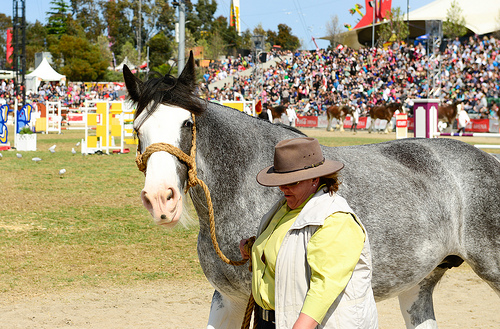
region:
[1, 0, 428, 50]
blue of daytime sky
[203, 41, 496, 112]
crowd sitting in stands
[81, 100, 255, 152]
white poles on yellow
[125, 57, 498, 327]
side of walking horse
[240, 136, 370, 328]
woman with rope in hand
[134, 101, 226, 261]
rope tied to horse head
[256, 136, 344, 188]
hat on woman's head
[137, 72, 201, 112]
black mane on head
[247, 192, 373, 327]
open vest on woman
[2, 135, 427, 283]
green grass on field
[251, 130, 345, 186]
Brown hat on woman's head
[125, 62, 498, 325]
Grey, white and black horse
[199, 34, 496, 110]
A large amount of fans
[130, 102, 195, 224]
White face of horse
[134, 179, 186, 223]
Pink nose of horse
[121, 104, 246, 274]
Tan rope on horses face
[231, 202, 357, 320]
Neon yellow button down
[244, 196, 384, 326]
White vest on woman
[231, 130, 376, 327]
Woman walking the horse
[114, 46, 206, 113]
Black hair on horses head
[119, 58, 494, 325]
Grey, black and white horse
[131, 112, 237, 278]
Beige rope on horse's face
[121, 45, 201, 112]
Black hair on horse's head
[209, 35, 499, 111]
A large group of fans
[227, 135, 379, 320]
the woman beside the horse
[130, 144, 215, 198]
the rope on the horse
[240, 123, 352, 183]
the woman wearing the hat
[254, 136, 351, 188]
the hat is brown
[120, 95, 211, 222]
the horse has white snout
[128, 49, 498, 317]
the horse is gray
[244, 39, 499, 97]
people are spectating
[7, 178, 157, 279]
the grass is short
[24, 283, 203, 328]
sand beside the horse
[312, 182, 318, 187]
the earring on the ear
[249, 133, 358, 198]
brown hat on woman's head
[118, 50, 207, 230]
white and black face on a horse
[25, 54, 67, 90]
white concessions tent in distance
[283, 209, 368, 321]
three quarter sleeve yellow shirt on woman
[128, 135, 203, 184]
yellowish gold bridel rope on horses face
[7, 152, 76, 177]
white pigeons on the ground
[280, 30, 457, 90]
audience in the distance watching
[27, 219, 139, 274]
grass growing on the ground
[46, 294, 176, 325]
sand with no grass on ground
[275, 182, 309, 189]
sunglasses on woman's face